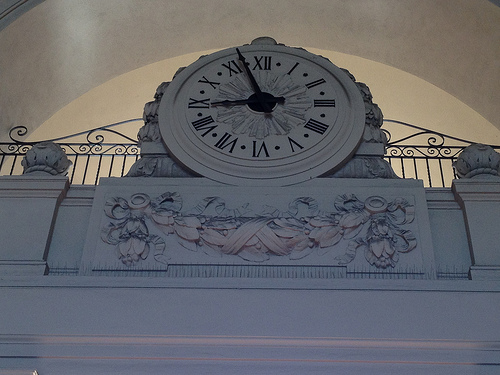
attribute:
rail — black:
[364, 126, 459, 183]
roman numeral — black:
[284, 136, 303, 153]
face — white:
[183, 50, 338, 162]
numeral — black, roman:
[189, 69, 229, 95]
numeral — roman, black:
[185, 116, 222, 145]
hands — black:
[231, 55, 278, 136]